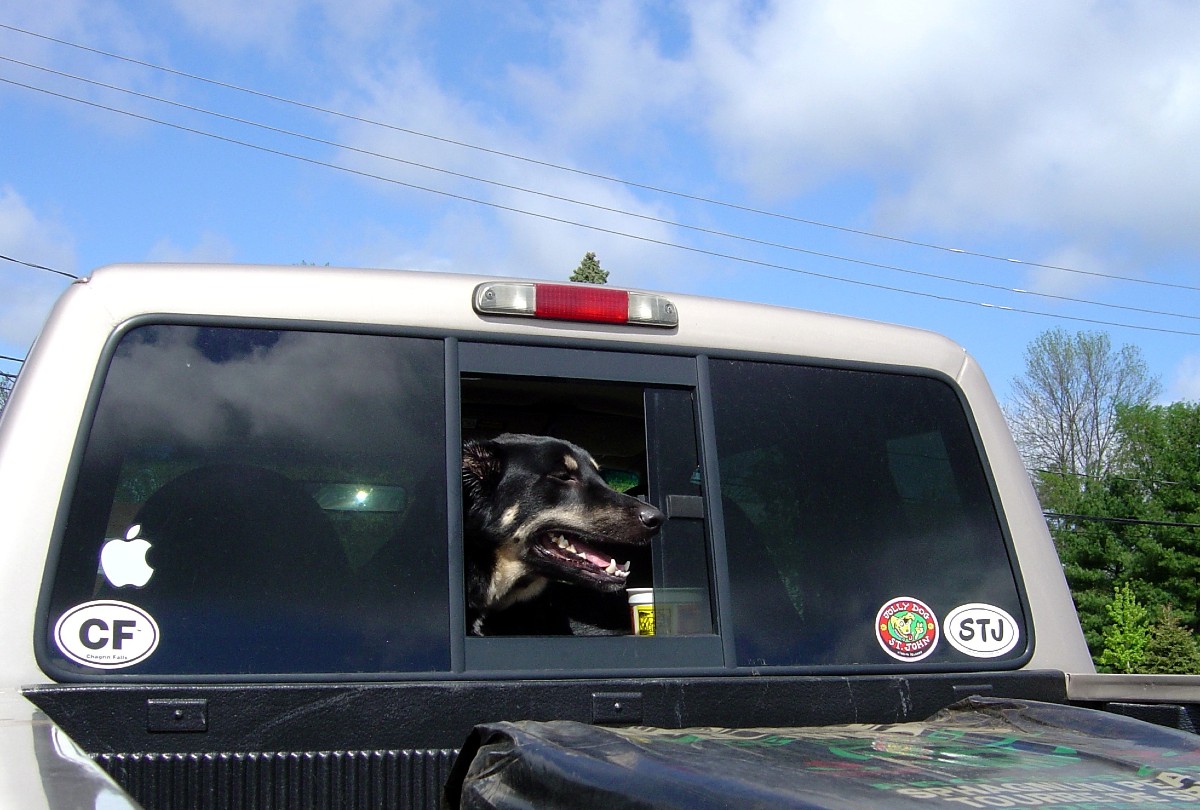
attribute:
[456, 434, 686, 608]
dog — riding, smelling, brown, looking, black, sticking, enjoying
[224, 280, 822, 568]
window — rear, open, tinted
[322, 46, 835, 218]
sky — white, light, blue, clear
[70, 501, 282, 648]
logo — popular, apple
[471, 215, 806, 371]
light — brake, red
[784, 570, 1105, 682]
sticks — bumper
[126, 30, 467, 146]
lines — streaking, electric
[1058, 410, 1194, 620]
trees — evergreen, side, distant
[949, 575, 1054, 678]
sticker — stj, red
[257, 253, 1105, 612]
truck — tinted, white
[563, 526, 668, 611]
tongue — pink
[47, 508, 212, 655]
decal — apple, lettered, cf, green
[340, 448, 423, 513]
mirror — reflecting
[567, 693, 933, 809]
tarp — plastic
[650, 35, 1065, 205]
clouds — puffy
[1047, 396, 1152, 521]
leaves — green